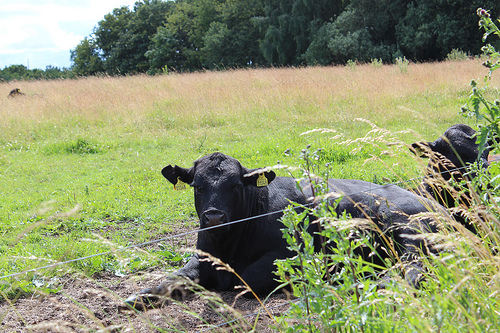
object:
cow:
[155, 152, 466, 296]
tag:
[256, 173, 269, 187]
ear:
[248, 167, 277, 189]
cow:
[413, 126, 498, 206]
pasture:
[3, 56, 499, 332]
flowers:
[393, 206, 497, 286]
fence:
[1, 154, 498, 327]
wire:
[0, 157, 497, 281]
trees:
[252, 0, 300, 63]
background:
[0, 0, 499, 85]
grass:
[0, 56, 496, 121]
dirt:
[7, 269, 291, 332]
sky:
[4, 3, 139, 69]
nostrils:
[203, 213, 210, 222]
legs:
[241, 250, 323, 298]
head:
[158, 150, 274, 231]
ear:
[160, 163, 190, 186]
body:
[197, 179, 450, 292]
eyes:
[190, 182, 204, 193]